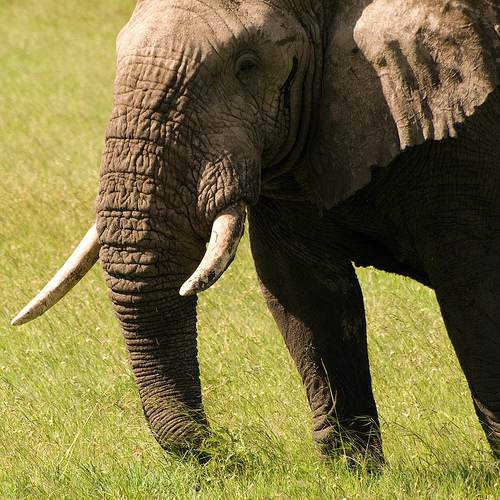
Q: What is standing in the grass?
A: Elephant.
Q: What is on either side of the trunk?
A: Tusks.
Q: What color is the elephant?
A: Gray.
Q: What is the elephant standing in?
A: Grass.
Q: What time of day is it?
A: Afternoon.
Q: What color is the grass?
A: Light green.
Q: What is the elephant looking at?
A: Camera.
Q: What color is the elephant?
A: Grey.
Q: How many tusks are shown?
A: Two.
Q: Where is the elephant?
A: On a field.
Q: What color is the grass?
A: Green.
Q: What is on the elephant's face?
A: Wrinkles.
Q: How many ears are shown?
A: One.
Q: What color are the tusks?
A: White.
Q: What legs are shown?
A: Front legs.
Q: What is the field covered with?
A: Grass.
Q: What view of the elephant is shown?
A: Front view.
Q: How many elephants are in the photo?
A: One.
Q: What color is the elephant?
A: Grey.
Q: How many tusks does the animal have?
A: Two.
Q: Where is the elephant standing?
A: Outside in grass.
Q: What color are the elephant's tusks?
A: White.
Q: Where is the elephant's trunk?
A: In the grass.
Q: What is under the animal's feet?
A: Grass.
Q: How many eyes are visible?
A: One.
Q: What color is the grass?
A: Green.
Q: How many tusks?
A: 2.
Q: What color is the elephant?
A: Gray.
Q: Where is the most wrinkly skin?
A: On the trunk.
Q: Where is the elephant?
A: In the grass.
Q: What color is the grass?
A: Green.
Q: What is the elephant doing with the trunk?
A: Pulling grass.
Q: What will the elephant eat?
A: The grass.